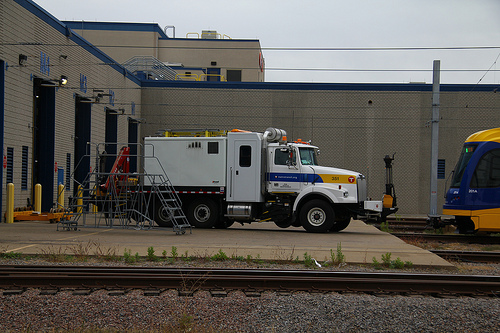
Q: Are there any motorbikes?
A: No, there are no motorbikes.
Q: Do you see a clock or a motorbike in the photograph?
A: No, there are no motorcycles or clocks.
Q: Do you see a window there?
A: Yes, there is a window.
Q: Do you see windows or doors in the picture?
A: Yes, there is a window.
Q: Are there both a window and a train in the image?
A: Yes, there are both a window and a train.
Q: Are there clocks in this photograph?
A: No, there are no clocks.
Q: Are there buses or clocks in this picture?
A: No, there are no clocks or buses.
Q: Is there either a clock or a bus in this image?
A: No, there are no clocks or buses.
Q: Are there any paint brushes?
A: No, there are no paint brushes.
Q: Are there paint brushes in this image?
A: No, there are no paint brushes.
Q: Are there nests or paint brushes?
A: No, there are no paint brushes or nests.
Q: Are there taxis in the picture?
A: Yes, there is a taxi.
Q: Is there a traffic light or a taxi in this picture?
A: Yes, there is a taxi.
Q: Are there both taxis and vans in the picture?
A: No, there is a taxi but no vans.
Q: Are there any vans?
A: No, there are no vans.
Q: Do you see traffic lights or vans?
A: No, there are no vans or traffic lights.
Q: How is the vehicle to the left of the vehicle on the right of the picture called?
A: The vehicle is a taxi.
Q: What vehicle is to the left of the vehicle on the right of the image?
A: The vehicle is a taxi.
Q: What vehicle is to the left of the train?
A: The vehicle is a taxi.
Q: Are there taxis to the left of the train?
A: Yes, there is a taxi to the left of the train.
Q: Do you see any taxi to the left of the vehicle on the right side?
A: Yes, there is a taxi to the left of the train.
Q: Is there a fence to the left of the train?
A: No, there is a taxi to the left of the train.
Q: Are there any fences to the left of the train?
A: No, there is a taxi to the left of the train.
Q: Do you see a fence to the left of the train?
A: No, there is a taxi to the left of the train.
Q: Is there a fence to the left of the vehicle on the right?
A: No, there is a taxi to the left of the train.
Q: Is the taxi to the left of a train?
A: Yes, the taxi is to the left of a train.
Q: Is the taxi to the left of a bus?
A: No, the taxi is to the left of a train.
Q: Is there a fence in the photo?
A: No, there are no fences.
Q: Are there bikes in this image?
A: No, there are no bikes.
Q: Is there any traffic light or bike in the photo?
A: No, there are no bikes or traffic lights.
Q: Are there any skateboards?
A: No, there are no skateboards.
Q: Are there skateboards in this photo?
A: No, there are no skateboards.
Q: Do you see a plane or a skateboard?
A: No, there are no skateboards or airplanes.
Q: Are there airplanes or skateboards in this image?
A: No, there are no skateboards or airplanes.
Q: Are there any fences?
A: No, there are no fences.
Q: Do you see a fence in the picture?
A: No, there are no fences.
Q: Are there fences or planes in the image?
A: No, there are no fences or planes.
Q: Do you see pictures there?
A: No, there are no pictures.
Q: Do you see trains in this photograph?
A: Yes, there is a train.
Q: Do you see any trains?
A: Yes, there is a train.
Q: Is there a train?
A: Yes, there is a train.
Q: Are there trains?
A: Yes, there is a train.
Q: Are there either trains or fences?
A: Yes, there is a train.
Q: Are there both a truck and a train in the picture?
A: Yes, there are both a train and a truck.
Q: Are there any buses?
A: No, there are no buses.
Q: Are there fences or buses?
A: No, there are no buses or fences.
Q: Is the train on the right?
A: Yes, the train is on the right of the image.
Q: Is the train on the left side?
A: No, the train is on the right of the image.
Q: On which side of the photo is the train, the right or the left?
A: The train is on the right of the image.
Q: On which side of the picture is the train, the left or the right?
A: The train is on the right of the image.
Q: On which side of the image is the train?
A: The train is on the right of the image.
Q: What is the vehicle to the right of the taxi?
A: The vehicle is a train.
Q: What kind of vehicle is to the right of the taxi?
A: The vehicle is a train.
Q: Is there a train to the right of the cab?
A: Yes, there is a train to the right of the cab.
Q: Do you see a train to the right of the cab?
A: Yes, there is a train to the right of the cab.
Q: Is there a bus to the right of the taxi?
A: No, there is a train to the right of the taxi.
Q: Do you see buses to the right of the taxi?
A: No, there is a train to the right of the taxi.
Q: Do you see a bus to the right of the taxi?
A: No, there is a train to the right of the taxi.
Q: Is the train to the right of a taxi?
A: Yes, the train is to the right of a taxi.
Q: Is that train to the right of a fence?
A: No, the train is to the right of a taxi.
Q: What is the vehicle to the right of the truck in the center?
A: The vehicle is a train.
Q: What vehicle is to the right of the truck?
A: The vehicle is a train.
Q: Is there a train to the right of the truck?
A: Yes, there is a train to the right of the truck.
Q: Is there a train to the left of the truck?
A: No, the train is to the right of the truck.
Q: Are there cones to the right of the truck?
A: No, there is a train to the right of the truck.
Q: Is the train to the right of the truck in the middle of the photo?
A: Yes, the train is to the right of the truck.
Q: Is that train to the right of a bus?
A: No, the train is to the right of the truck.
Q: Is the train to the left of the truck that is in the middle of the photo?
A: No, the train is to the right of the truck.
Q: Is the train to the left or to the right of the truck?
A: The train is to the right of the truck.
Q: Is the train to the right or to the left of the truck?
A: The train is to the right of the truck.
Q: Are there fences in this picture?
A: No, there are no fences.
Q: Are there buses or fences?
A: No, there are no fences or buses.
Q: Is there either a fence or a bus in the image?
A: No, there are no fences or buses.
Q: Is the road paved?
A: Yes, the road is paved.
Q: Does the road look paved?
A: Yes, the road is paved.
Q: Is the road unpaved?
A: No, the road is paved.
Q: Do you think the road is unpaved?
A: No, the road is paved.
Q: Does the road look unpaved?
A: No, the road is paved.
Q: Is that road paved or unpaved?
A: The road is paved.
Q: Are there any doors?
A: Yes, there is a door.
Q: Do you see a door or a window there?
A: Yes, there is a door.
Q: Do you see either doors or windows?
A: Yes, there is a door.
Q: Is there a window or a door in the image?
A: Yes, there is a door.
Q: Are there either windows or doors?
A: Yes, there is a door.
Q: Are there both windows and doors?
A: Yes, there are both a door and a window.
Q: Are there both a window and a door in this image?
A: Yes, there are both a door and a window.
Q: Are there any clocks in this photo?
A: No, there are no clocks.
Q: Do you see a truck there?
A: Yes, there is a truck.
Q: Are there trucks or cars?
A: Yes, there is a truck.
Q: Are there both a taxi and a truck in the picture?
A: Yes, there are both a truck and a taxi.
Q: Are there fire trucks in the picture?
A: No, there are no fire trucks.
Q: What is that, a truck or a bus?
A: That is a truck.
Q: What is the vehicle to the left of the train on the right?
A: The vehicle is a truck.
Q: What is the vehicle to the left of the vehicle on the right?
A: The vehicle is a truck.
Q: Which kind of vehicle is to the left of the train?
A: The vehicle is a truck.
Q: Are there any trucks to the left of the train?
A: Yes, there is a truck to the left of the train.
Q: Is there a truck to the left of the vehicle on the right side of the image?
A: Yes, there is a truck to the left of the train.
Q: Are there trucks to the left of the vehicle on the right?
A: Yes, there is a truck to the left of the train.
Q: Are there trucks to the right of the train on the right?
A: No, the truck is to the left of the train.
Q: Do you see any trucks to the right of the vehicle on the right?
A: No, the truck is to the left of the train.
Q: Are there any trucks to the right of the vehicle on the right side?
A: No, the truck is to the left of the train.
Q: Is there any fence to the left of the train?
A: No, there is a truck to the left of the train.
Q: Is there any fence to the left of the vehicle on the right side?
A: No, there is a truck to the left of the train.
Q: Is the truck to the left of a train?
A: Yes, the truck is to the left of a train.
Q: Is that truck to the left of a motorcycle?
A: No, the truck is to the left of a train.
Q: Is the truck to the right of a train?
A: No, the truck is to the left of a train.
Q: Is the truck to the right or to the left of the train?
A: The truck is to the left of the train.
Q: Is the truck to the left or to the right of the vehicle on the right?
A: The truck is to the left of the train.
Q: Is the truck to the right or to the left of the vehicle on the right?
A: The truck is to the left of the train.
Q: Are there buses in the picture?
A: No, there are no buses.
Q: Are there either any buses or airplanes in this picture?
A: No, there are no buses or airplanes.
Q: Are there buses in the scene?
A: No, there are no buses.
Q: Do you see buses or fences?
A: No, there are no buses or fences.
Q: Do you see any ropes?
A: No, there are no ropes.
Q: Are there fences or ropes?
A: No, there are no ropes or fences.